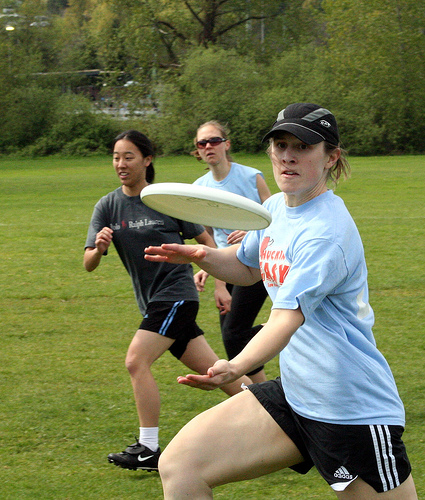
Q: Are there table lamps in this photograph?
A: No, there are no table lamps.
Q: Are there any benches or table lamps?
A: No, there are no table lamps or benches.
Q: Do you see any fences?
A: No, there are no fences.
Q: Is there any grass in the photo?
A: Yes, there is grass.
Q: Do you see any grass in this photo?
A: Yes, there is grass.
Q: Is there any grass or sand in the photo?
A: Yes, there is grass.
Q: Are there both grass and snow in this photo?
A: No, there is grass but no snow.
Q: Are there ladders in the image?
A: No, there are no ladders.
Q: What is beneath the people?
A: The grass is beneath the people.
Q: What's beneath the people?
A: The grass is beneath the people.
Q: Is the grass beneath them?
A: Yes, the grass is beneath the people.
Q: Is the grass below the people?
A: Yes, the grass is below the people.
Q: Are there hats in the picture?
A: Yes, there is a hat.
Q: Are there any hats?
A: Yes, there is a hat.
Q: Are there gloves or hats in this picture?
A: Yes, there is a hat.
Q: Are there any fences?
A: No, there are no fences.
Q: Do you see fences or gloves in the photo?
A: No, there are no fences or gloves.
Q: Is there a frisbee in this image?
A: Yes, there is a frisbee.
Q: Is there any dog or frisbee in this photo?
A: Yes, there is a frisbee.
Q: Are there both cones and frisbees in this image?
A: No, there is a frisbee but no cones.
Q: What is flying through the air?
A: The frisbee is flying through the air.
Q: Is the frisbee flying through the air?
A: Yes, the frisbee is flying through the air.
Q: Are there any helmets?
A: No, there are no helmets.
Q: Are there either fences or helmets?
A: No, there are no helmets or fences.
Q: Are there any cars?
A: No, there are no cars.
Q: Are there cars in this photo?
A: No, there are no cars.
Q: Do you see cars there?
A: No, there are no cars.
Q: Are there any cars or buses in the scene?
A: No, there are no cars or buses.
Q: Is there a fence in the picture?
A: No, there are no fences.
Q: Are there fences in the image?
A: No, there are no fences.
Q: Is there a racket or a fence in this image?
A: No, there are no fences or rackets.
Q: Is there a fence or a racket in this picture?
A: No, there are no fences or rackets.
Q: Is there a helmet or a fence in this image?
A: No, there are no fences or helmets.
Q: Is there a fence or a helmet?
A: No, there are no fences or helmets.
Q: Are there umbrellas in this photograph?
A: No, there are no umbrellas.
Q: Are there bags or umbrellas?
A: No, there are no umbrellas or bags.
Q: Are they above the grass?
A: Yes, the people are above the grass.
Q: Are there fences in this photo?
A: No, there are no fences.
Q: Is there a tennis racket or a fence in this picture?
A: No, there are no fences or rackets.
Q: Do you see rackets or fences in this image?
A: No, there are no fences or rackets.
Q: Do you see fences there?
A: No, there are no fences.